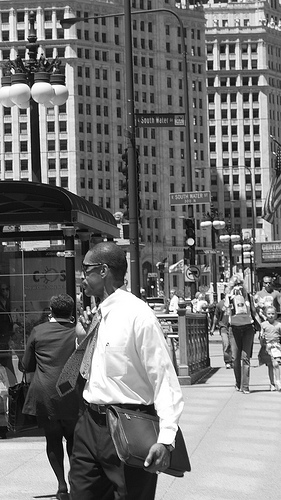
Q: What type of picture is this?
A: Black and white.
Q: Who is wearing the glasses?
A: The man.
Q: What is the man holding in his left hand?
A: A satchel.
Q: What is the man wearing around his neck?
A: A tie.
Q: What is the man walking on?
A: The sidewalk.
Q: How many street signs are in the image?
A: Two.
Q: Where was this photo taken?
A: A city.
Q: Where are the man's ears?
A: On his head.